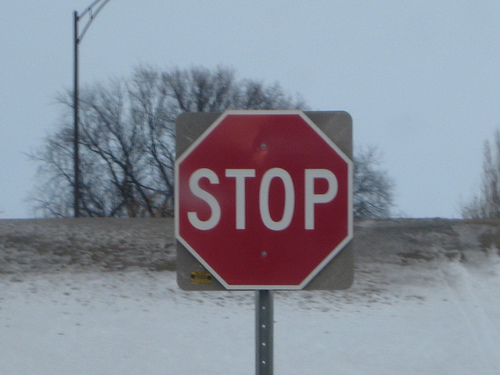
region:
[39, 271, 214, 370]
patch of snow behind the stop sign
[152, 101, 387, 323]
red stop sign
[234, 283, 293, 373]
silver pole emerging from the ground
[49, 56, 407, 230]
tree with no leaves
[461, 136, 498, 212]
shrubbery with no leaves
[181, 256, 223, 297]
yellow sticker on the sign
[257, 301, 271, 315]
holes in the pole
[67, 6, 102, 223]
light pole next to the tree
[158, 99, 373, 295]
square sign behind stop sign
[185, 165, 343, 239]
letters on the stop sign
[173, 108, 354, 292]
The stop sign is red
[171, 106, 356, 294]
The stop sign has the word stop printed on it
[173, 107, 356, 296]
The stop sign is against another square sign behind it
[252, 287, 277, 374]
The sign is on a metal post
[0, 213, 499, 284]
The grass is brown and dry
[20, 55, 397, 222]
The trees behind the sign are leafless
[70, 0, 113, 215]
The light post is in front of the trees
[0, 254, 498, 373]
The ground has a sandy area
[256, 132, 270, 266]
The stop sign has metal screws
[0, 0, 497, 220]
The sky is bright and clear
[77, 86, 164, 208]
Barren branches on tree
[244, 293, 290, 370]
Metal pole holding sign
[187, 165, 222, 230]
Letter S in white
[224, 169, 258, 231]
Letter T in white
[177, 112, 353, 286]
Red octagon stop sign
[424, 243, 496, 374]
Car tracks in the snow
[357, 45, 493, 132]
snowy clouds in the sky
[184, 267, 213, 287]
Yellow sticker on sign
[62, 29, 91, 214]
Telephone pole in front of trees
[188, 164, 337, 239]
the word stop on a sign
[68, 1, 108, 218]
Light pole in the back of the stop sign.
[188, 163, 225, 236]
The letter S on the stop sign.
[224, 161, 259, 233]
The letter T on the stop sign.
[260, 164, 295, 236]
The letter O on the stop sign.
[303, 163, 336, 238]
The letter P on the stop sign.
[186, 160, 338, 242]
The word Stop on the stop sign.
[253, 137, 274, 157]
The top screw holding the stop sign up.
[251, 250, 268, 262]
The bottom screw holding the stop sign up.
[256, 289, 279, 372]
The metal pole the stop sign is mounted on.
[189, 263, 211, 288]
The yellow and black sticker to the left of the stop sign on the back of the square sign.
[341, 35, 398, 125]
clouds are in the sky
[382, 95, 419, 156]
the clouds are grey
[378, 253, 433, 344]
snow covers the ground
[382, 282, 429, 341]
the snow is white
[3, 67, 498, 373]
it is winter season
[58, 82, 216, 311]
the trees are dry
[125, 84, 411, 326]
the stop sign is red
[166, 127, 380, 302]
stop is written in white in the sign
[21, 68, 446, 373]
it is a daytime scene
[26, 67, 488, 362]
it is an outdoor scene